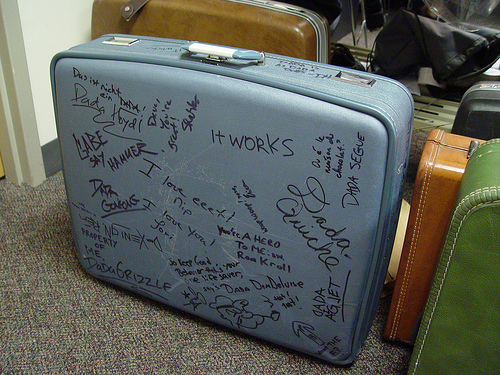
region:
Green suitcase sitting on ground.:
[422, 245, 493, 359]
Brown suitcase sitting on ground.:
[410, 137, 445, 282]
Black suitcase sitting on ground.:
[456, 84, 496, 126]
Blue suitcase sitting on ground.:
[133, 68, 250, 216]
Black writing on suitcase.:
[75, 86, 341, 316]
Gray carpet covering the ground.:
[24, 253, 124, 348]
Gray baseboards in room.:
[46, 143, 62, 175]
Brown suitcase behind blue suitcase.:
[226, 7, 316, 59]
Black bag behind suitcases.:
[376, 7, 498, 110]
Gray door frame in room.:
[3, 63, 74, 230]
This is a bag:
[45, 28, 416, 362]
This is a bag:
[81, 0, 346, 81]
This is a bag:
[394, 125, 488, 357]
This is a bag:
[444, 79, 498, 143]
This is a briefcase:
[35, 29, 417, 373]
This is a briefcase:
[85, 2, 347, 83]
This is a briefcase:
[405, 138, 497, 370]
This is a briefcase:
[438, 75, 498, 172]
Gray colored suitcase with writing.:
[69, 39, 391, 366]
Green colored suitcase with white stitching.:
[459, 144, 497, 371]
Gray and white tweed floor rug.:
[12, 228, 59, 369]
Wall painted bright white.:
[39, 6, 53, 133]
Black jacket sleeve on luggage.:
[376, 9, 498, 79]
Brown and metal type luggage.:
[88, 0, 327, 39]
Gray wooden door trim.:
[9, 12, 36, 179]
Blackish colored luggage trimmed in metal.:
[453, 79, 498, 130]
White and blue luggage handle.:
[181, 42, 273, 62]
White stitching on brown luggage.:
[406, 150, 435, 270]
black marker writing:
[79, 81, 203, 158]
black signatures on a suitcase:
[226, 203, 343, 287]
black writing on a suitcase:
[176, 251, 283, 310]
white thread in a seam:
[444, 247, 453, 262]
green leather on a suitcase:
[449, 240, 490, 328]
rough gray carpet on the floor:
[32, 295, 109, 365]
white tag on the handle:
[185, 36, 231, 60]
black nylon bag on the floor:
[374, 11, 487, 81]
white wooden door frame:
[1, 61, 46, 188]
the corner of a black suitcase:
[451, 77, 496, 127]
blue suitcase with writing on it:
[48, 30, 417, 369]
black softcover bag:
[366, 7, 495, 86]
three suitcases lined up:
[381, 78, 496, 370]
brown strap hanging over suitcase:
[115, 2, 150, 23]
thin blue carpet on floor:
[5, 170, 411, 370]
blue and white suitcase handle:
[179, 37, 266, 72]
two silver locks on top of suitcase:
[101, 33, 376, 90]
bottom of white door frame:
[3, 5, 48, 197]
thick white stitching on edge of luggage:
[383, 126, 446, 344]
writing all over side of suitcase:
[70, 64, 367, 356]